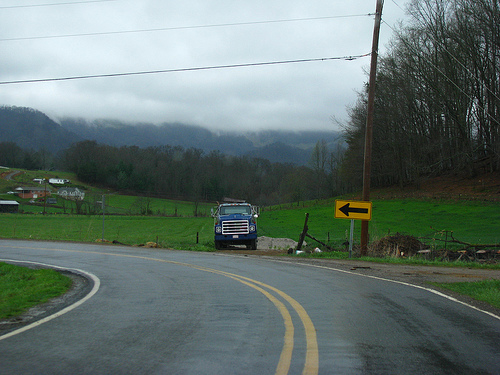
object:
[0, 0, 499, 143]
sky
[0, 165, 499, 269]
grass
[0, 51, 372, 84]
electrical line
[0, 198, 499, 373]
ground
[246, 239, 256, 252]
tire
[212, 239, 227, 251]
tire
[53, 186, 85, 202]
house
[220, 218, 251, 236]
grill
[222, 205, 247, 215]
window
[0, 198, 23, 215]
houses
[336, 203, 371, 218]
arrow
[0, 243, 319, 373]
stripes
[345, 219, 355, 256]
pole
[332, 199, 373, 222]
sign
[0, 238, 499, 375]
road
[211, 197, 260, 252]
car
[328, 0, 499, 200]
trees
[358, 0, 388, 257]
pole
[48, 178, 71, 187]
house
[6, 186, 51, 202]
house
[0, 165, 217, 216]
hills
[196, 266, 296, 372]
lines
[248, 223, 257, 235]
headlights